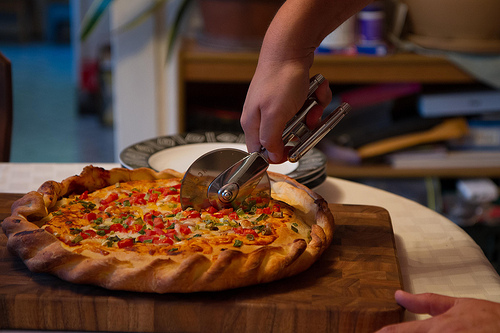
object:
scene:
[0, 0, 500, 333]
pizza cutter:
[178, 74, 352, 213]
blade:
[179, 147, 274, 212]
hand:
[237, 62, 332, 163]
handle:
[285, 101, 353, 164]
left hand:
[374, 288, 500, 333]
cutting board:
[0, 189, 407, 333]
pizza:
[0, 164, 337, 296]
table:
[0, 161, 500, 333]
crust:
[55, 255, 123, 284]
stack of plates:
[116, 130, 329, 192]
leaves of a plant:
[78, 1, 113, 47]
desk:
[179, 37, 500, 85]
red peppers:
[154, 223, 165, 228]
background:
[0, 1, 499, 172]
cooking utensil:
[356, 117, 469, 158]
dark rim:
[298, 171, 307, 174]